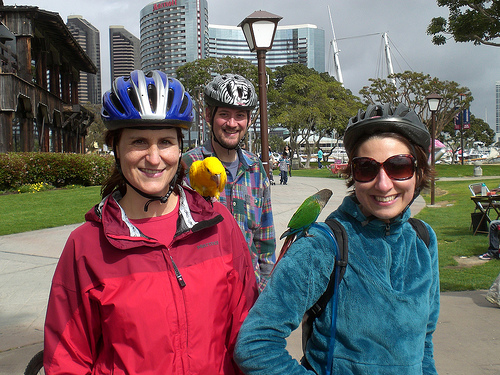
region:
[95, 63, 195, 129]
She has a blue helmet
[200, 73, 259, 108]
Gray helmet being worn by the man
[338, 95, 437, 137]
Gray helmet being worn by the woman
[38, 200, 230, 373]
A pink jacket worn by the woman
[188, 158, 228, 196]
Bird sitting on her shoulder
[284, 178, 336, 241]
Bird also sitting on her shoulder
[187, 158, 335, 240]
Two birds sit on their shoulders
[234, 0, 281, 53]
A lamp on top of the post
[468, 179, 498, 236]
A picnic table in the background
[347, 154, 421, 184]
Big sunglasses worn by the woman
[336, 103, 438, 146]
helmet on the person's head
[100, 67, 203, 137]
helmet on the person's head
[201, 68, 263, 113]
helmet on the person's head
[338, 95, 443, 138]
helmet on the woman's head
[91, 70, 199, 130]
helmet on the woman's head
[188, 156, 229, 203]
bird on woman's shoulder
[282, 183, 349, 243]
bird on woman's shoulder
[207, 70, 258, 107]
helmet on the man's head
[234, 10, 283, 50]
light fixture on top of pole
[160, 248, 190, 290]
zipper on woman's jacket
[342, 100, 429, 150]
Dark grey and black helmet.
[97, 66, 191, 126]
Blue and silver helmet.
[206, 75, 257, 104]
Silver helmet with black stripes.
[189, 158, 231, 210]
Yellow bird on woman's shoulder.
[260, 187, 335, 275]
Green bird on woman's shoulder.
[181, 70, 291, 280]
Man in checkered shirt.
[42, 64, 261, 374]
Woman wearing red jacket.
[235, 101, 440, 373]
Woman wearing blue jacket.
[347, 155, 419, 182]
Brown sunglasses worn by woman.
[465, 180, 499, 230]
Metal folding chair in grass.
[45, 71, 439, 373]
three people standing on a road in a park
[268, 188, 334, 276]
a green parrot on woman's shoulder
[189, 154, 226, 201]
a yellow parrot on woman's shoulder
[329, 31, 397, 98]
two white masts of a ship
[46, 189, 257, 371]
woman wearing a pink windbreaker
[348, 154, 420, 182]
woman wearing big brown sunglasses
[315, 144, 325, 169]
man wearing blue standing in a park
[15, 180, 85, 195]
yellow flowers on a lawn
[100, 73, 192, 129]
woman wearing a blue nd white helmet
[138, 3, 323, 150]
a silver round shaped building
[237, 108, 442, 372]
Woman wearing a blue sweater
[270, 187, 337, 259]
Bird on the woman's shoulder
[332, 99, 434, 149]
Helmet on the woman's head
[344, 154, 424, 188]
Sunglasses on the woman's face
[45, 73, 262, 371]
Woman wearing a red jacket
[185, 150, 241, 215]
Bird on the woman's shoulders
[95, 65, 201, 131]
Helmet on the woman's head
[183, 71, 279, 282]
Man standing behind the women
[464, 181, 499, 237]
Table and chair on grass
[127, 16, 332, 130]
Building in the background